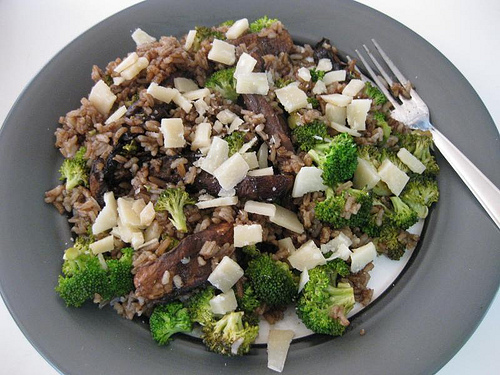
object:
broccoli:
[312, 182, 373, 230]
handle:
[424, 125, 500, 228]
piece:
[269, 237, 376, 339]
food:
[388, 79, 412, 102]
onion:
[268, 330, 295, 372]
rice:
[116, 288, 144, 316]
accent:
[387, 264, 422, 309]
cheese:
[161, 118, 186, 149]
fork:
[344, 37, 499, 232]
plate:
[2, 2, 500, 375]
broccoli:
[298, 278, 358, 336]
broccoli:
[204, 312, 260, 360]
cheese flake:
[207, 254, 245, 293]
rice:
[145, 41, 199, 79]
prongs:
[340, 36, 432, 131]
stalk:
[328, 279, 360, 309]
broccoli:
[296, 267, 356, 338]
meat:
[122, 219, 249, 305]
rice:
[132, 153, 185, 193]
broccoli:
[388, 196, 418, 231]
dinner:
[48, 19, 441, 365]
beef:
[244, 94, 297, 155]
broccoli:
[306, 131, 359, 187]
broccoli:
[54, 245, 133, 309]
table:
[1, 3, 483, 372]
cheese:
[213, 152, 250, 189]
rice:
[192, 208, 242, 230]